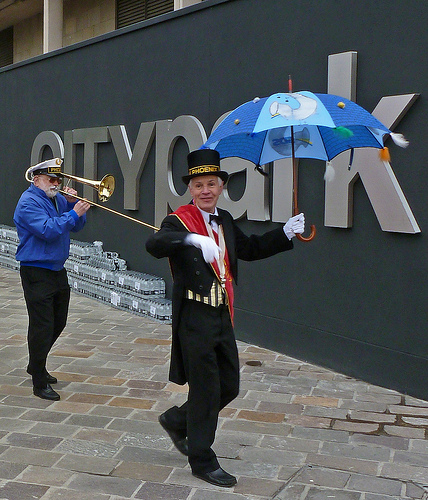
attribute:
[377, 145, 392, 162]
feather — small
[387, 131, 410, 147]
feather — small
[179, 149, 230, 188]
top hat — black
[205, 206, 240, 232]
tie — black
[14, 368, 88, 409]
man's foot —  man's, with shoe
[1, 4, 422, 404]
sign — large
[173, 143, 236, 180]
hat —  man's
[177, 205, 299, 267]
gloves —  man's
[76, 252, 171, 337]
bottles —  of water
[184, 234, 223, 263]
gloves — white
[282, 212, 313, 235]
gloves — white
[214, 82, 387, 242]
umbrella — blue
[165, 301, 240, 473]
pants —  black,  man's